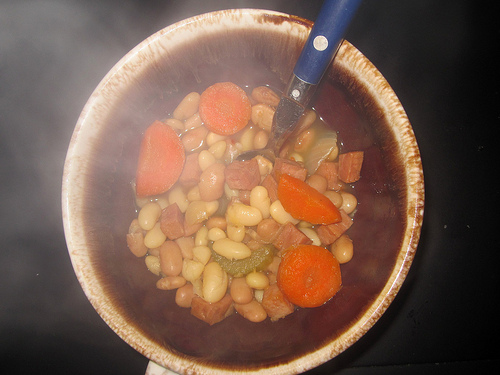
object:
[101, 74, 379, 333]
soup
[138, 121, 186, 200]
carrot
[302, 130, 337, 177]
paprika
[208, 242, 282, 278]
paprika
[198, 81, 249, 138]
carrot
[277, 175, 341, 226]
carrot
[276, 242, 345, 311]
carrot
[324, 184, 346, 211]
ground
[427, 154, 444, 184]
ground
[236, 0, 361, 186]
spoon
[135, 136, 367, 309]
garbage cans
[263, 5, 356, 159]
handle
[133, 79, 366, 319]
vegetable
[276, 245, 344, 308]
piece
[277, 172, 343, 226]
piece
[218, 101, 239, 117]
piece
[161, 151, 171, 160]
piece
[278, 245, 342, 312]
caroot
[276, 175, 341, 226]
caroot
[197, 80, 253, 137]
caroot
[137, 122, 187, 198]
caroot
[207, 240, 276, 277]
green vegetable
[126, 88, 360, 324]
beans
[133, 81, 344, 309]
carrot stew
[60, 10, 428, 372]
bowl